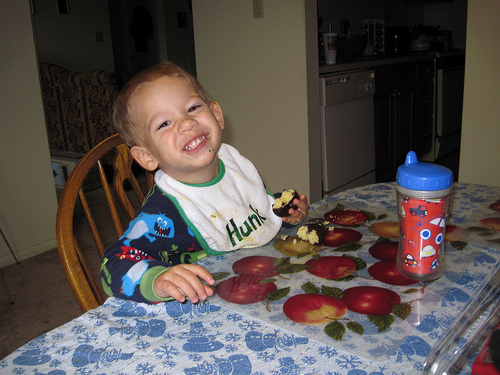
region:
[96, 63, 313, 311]
small boy in bib at table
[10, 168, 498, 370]
blue and white tablecloth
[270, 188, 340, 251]
small black bowl of scrambled egg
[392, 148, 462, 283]
clear plastic cup with blue sippie lid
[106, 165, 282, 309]
baby wearing green and blue monster pajamas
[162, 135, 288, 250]
white bib lined in green with green Hunk written across it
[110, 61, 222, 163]
boy has short blond curly hair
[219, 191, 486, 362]
clear place mat with red apples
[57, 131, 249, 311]
brown wooden chair with boy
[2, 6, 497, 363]
indoor kitchen scene with baby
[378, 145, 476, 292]
This is a red and blue cup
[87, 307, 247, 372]
Cloth on the table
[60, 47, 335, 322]
This is a white boy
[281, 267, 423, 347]
Apples on the table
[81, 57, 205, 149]
Hair is short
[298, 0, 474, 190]
This is the kitchen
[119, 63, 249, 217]
boy smiling at camera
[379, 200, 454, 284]
cars on sippy cup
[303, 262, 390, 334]
apples on placemat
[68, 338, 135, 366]
blue snowmen on table cloth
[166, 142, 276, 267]
white and green baby bib around boys neck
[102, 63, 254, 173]
boy with blonde hair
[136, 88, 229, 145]
boy with brown eyes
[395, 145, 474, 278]
sippy cup with blue lid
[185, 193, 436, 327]
placemat with apples on it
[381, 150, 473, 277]
sippy cup with a blue lid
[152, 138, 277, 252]
baby bib around child neck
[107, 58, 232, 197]
boy with blonde hair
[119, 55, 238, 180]
boy smiling at camera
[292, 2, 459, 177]
kitchen in the background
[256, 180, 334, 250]
boy eating a small donut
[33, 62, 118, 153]
couch with floral design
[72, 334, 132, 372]
blue snowmen on table cloth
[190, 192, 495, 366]
clear plastic place mat with apples on it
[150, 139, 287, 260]
white bib with green edges and writing on it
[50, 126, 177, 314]
brown wooden table chair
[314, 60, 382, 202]
white under counter dishwasher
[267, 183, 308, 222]
half eaten chocolate covered doughnut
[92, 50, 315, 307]
little boy smiling and eating doughnut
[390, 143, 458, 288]
child's red sippy cup with blue lid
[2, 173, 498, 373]
white table cloth with blue snowmen on it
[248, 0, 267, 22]
light switch with white plastic cover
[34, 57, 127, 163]
back side of cream colored couch with striped style pattern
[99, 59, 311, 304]
small white kid in chair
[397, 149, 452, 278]
tall large red and blue cup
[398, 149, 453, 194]
large round blue cup lid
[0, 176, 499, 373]
large blue cloth table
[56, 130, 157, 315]
large wooden brown chair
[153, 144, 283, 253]
large thin cloth white bib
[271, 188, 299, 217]
crushed white food in hand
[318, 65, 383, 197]
large white square machine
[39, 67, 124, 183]
large floral cloth couch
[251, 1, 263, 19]
small square white light switch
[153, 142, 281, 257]
white bib that says hunk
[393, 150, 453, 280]
red sippy cup with a blue lid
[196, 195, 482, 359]
clear place mat with apples